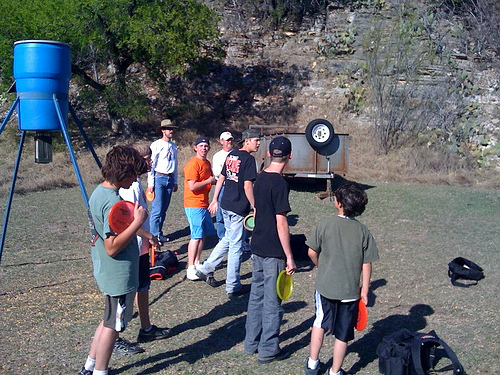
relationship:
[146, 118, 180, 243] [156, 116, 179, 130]
man wearing hat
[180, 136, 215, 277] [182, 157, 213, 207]
man wearing shirt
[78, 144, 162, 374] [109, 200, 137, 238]
person holding frisbee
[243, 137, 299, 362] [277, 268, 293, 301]
guy holding frisbee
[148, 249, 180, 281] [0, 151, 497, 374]
bag on ground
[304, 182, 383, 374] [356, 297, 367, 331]
boy holding frisbee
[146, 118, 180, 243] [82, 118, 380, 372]
man in group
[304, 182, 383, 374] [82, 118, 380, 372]
boy in group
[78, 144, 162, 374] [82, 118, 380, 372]
person in group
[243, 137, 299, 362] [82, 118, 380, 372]
guy in group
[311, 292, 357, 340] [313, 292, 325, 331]
shorts have stripe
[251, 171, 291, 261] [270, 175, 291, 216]
tee shirt has sleeve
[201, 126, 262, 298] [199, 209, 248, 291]
boy wearing jeans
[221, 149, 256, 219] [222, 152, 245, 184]
tee shirt with graphics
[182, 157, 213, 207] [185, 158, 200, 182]
shirt has sleeve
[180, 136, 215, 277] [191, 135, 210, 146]
man wearing cap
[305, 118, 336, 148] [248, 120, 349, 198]
tire on trailer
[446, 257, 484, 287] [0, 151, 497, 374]
bag on ground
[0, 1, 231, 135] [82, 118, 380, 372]
tree side of group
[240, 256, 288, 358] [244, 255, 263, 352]
pants have leg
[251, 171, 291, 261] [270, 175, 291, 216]
shirt has sleeve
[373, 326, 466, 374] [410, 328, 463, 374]
bag has handle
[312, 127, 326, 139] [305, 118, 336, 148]
wheel has tire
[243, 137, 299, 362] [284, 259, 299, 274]
guy has hand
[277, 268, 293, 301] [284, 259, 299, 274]
frisbee in hand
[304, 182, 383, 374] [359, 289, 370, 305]
boy has hand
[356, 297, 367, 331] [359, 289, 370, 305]
frisbee in hand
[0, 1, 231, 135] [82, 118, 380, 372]
tree behind group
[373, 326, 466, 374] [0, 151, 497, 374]
bag on ground